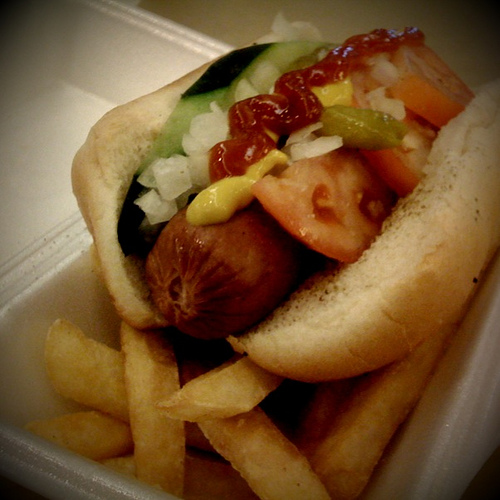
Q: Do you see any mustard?
A: Yes, there is mustard.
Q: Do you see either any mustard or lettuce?
A: Yes, there is mustard.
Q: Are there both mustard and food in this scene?
A: Yes, there are both mustard and food.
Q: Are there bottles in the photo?
A: No, there are no bottles.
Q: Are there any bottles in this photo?
A: No, there are no bottles.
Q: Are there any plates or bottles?
A: No, there are no bottles or plates.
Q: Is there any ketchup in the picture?
A: Yes, there is ketchup.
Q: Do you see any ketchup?
A: Yes, there is ketchup.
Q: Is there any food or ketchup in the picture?
A: Yes, there is ketchup.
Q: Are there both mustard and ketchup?
A: Yes, there are both ketchup and mustard.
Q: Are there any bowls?
A: No, there are no bowls.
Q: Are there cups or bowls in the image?
A: No, there are no bowls or cups.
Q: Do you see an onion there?
A: Yes, there are onions.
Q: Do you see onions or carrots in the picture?
A: Yes, there are onions.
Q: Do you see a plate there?
A: No, there are no plates.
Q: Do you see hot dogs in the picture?
A: Yes, there is a hot dog.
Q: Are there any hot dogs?
A: Yes, there is a hot dog.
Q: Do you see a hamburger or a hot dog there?
A: Yes, there is a hot dog.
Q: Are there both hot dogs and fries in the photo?
A: Yes, there are both a hot dog and fries.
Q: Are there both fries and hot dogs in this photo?
A: Yes, there are both a hot dog and fries.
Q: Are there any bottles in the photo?
A: No, there are no bottles.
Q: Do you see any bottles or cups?
A: No, there are no bottles or cups.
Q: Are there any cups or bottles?
A: No, there are no bottles or cups.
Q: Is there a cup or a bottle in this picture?
A: No, there are no bottles or cups.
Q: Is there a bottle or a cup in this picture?
A: No, there are no bottles or cups.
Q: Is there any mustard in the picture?
A: Yes, there is mustard.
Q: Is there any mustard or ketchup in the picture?
A: Yes, there is mustard.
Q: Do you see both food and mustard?
A: Yes, there are both mustard and food.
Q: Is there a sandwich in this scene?
A: Yes, there is a sandwich.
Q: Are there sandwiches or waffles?
A: Yes, there is a sandwich.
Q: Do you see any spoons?
A: No, there are no spoons.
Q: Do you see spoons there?
A: No, there are no spoons.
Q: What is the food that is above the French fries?
A: The food is a sandwich.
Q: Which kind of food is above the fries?
A: The food is a sandwich.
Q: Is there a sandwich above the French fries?
A: Yes, there is a sandwich above the French fries.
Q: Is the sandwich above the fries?
A: Yes, the sandwich is above the fries.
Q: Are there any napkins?
A: No, there are no napkins.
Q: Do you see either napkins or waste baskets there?
A: No, there are no napkins or waste baskets.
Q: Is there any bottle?
A: No, there are no bottles.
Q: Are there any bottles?
A: No, there are no bottles.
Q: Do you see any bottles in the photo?
A: No, there are no bottles.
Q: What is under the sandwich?
A: The fries are under the sandwich.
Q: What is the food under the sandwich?
A: The food is fries.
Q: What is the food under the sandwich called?
A: The food is fries.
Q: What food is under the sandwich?
A: The food is fries.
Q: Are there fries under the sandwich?
A: Yes, there are fries under the sandwich.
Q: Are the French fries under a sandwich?
A: Yes, the French fries are under a sandwich.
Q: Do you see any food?
A: Yes, there is food.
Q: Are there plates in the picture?
A: No, there are no plates.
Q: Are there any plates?
A: No, there are no plates.